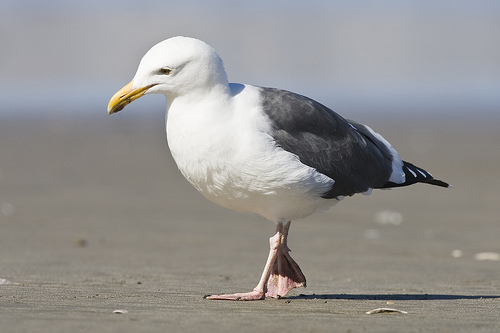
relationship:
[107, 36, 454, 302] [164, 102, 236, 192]
bird has chest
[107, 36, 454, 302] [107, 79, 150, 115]
bird has beak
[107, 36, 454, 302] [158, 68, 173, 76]
bird has eye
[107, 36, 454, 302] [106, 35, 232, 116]
bird has head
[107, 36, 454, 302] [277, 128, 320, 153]
bird has feather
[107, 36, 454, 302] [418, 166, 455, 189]
bird has tail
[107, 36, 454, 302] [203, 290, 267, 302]
bird has foot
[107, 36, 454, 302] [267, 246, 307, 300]
bird has foot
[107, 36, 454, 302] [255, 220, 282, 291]
bird has leg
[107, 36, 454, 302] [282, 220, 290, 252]
bird has leg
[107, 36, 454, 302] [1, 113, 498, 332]
bird standing on sand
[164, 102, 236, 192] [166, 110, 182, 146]
chest has feather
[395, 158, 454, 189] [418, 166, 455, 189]
tail has tail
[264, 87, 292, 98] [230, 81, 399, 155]
feather on back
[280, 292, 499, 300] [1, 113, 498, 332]
shadow on top of sand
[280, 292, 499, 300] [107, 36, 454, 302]
shadow from bird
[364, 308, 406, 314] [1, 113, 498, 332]
shell on top of sand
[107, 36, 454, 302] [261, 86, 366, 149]
bird has wing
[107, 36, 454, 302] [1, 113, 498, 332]
bird standing in sand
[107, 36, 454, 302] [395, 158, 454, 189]
bird has tail